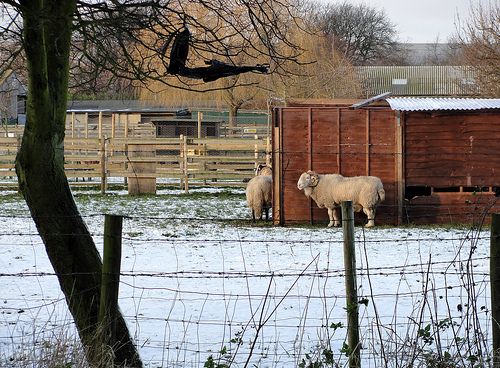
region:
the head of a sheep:
[288, 158, 336, 203]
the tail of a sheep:
[360, 178, 401, 205]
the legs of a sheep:
[317, 198, 351, 229]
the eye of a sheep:
[298, 153, 316, 195]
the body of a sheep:
[301, 153, 425, 212]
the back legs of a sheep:
[348, 202, 392, 237]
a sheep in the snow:
[278, 148, 425, 231]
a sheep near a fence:
[205, 81, 432, 231]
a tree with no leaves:
[159, 0, 299, 77]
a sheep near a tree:
[31, 128, 474, 323]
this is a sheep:
[287, 160, 387, 228]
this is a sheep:
[229, 146, 283, 225]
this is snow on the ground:
[208, 293, 288, 342]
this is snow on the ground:
[189, 265, 264, 318]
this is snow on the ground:
[349, 288, 426, 331]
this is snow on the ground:
[129, 261, 201, 327]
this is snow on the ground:
[197, 223, 267, 290]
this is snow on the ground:
[5, 259, 57, 320]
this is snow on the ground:
[165, 282, 223, 333]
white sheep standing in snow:
[296, 170, 388, 227]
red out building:
[269, 93, 499, 226]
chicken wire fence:
[1, 228, 498, 366]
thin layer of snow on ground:
[6, 195, 498, 366]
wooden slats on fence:
[5, 135, 262, 187]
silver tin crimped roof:
[385, 95, 499, 114]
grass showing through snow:
[8, 186, 265, 228]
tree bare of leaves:
[4, 2, 311, 94]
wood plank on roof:
[347, 88, 392, 108]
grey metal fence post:
[340, 196, 363, 366]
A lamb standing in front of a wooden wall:
[290, 168, 386, 227]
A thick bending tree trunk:
[3, 4, 133, 364]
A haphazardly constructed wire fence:
[180, 224, 498, 364]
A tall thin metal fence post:
[336, 205, 373, 365]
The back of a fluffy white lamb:
[242, 172, 271, 223]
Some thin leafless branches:
[183, 3, 296, 63]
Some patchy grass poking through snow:
[156, 195, 236, 214]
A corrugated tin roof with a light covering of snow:
[387, 97, 499, 109]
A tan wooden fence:
[104, 136, 231, 188]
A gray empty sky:
[402, 5, 447, 36]